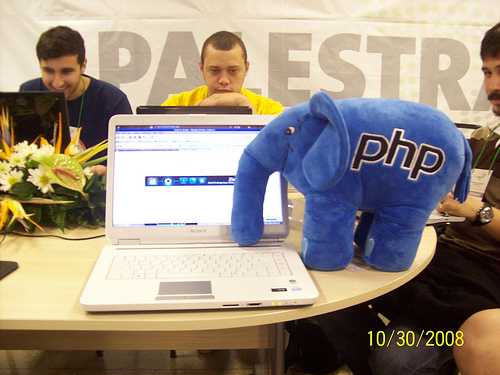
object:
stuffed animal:
[229, 89, 475, 273]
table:
[1, 192, 439, 374]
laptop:
[79, 113, 321, 311]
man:
[158, 29, 286, 116]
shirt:
[160, 85, 285, 119]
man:
[16, 25, 133, 177]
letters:
[346, 126, 446, 185]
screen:
[111, 125, 283, 227]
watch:
[469, 200, 494, 229]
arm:
[435, 192, 500, 239]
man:
[436, 21, 500, 375]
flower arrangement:
[1, 112, 109, 235]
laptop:
[1, 92, 71, 154]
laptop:
[136, 104, 253, 116]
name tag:
[466, 169, 494, 202]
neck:
[489, 116, 500, 122]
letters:
[96, 29, 494, 110]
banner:
[69, 21, 497, 112]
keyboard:
[103, 249, 294, 281]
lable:
[271, 288, 287, 293]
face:
[38, 54, 81, 98]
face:
[203, 49, 245, 96]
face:
[481, 60, 500, 117]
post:
[273, 319, 284, 375]